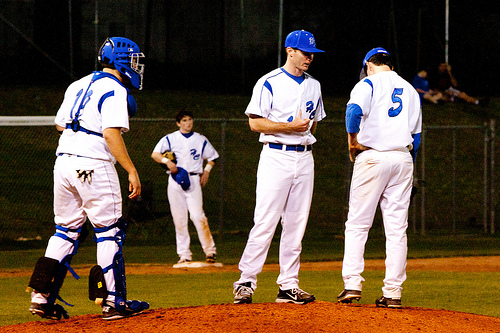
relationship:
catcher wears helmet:
[24, 26, 154, 316] [99, 37, 149, 83]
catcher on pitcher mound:
[24, 26, 154, 316] [0, 304, 497, 331]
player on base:
[149, 105, 229, 271] [168, 255, 224, 270]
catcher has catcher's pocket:
[24, 26, 154, 316] [73, 166, 100, 190]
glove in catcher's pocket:
[148, 174, 197, 193] [73, 166, 100, 190]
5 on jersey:
[387, 83, 404, 120] [351, 67, 423, 141]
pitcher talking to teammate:
[242, 16, 341, 318] [334, 43, 433, 300]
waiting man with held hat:
[149, 109, 221, 263] [169, 164, 191, 192]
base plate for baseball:
[167, 249, 227, 276] [14, 15, 481, 329]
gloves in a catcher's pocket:
[74, 167, 96, 184] [73, 170, 101, 192]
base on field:
[171, 260, 224, 270] [21, 190, 489, 312]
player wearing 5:
[335, 45, 422, 309] [387, 83, 404, 120]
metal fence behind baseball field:
[433, 117, 498, 240] [2, 61, 497, 329]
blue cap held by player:
[169, 167, 192, 191] [146, 107, 222, 259]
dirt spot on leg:
[196, 215, 219, 254] [187, 200, 233, 260]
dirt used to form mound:
[187, 310, 339, 331] [197, 305, 343, 329]